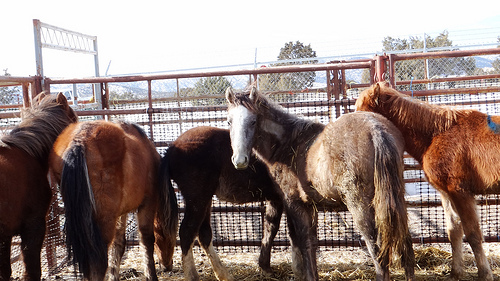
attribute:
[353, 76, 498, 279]
horse — brown 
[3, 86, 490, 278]
horses — outdoors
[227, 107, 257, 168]
face — white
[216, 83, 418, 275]
horse — brown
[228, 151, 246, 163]
nose — white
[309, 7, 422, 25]
sky — clear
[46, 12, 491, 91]
sky — bright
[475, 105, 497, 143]
print — blue 